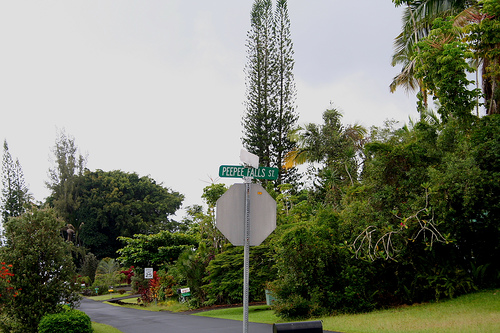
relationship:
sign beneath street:
[208, 181, 285, 253] [70, 272, 297, 331]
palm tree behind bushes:
[473, 4, 498, 116] [279, 126, 497, 323]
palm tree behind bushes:
[389, 17, 433, 123] [279, 126, 497, 323]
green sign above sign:
[218, 165, 279, 181] [210, 181, 276, 248]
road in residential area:
[74, 290, 274, 329] [3, 0, 498, 328]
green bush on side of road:
[36, 306, 93, 331] [52, 292, 339, 331]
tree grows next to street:
[264, 218, 337, 319] [70, 297, 274, 331]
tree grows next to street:
[193, 246, 274, 309] [70, 297, 274, 331]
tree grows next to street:
[118, 228, 202, 303] [70, 297, 274, 331]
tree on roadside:
[264, 218, 337, 319] [74, 296, 275, 331]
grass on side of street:
[209, 254, 487, 331] [70, 297, 274, 331]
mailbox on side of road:
[179, 283, 191, 296] [70, 297, 273, 331]